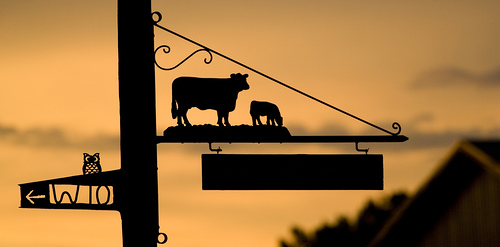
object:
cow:
[170, 72, 250, 127]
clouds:
[0, 65, 498, 148]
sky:
[2, 3, 499, 246]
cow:
[249, 100, 284, 126]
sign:
[19, 0, 409, 247]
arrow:
[24, 189, 46, 204]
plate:
[201, 142, 384, 191]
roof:
[371, 136, 500, 247]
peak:
[435, 137, 496, 167]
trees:
[277, 193, 409, 247]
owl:
[81, 152, 103, 175]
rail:
[158, 135, 410, 143]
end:
[392, 122, 402, 136]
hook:
[157, 233, 169, 245]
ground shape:
[161, 124, 292, 138]